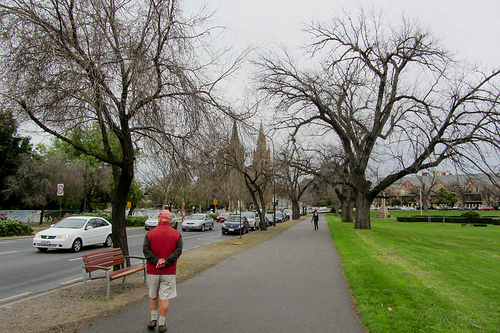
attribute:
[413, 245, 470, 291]
grass — green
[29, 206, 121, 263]
car — white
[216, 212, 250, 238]
car — black, parked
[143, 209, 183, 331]
man — wearing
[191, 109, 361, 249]
building — large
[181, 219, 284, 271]
grass — mostly dead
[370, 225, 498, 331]
grass — green, trim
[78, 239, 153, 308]
bench — red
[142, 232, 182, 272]
vest — red